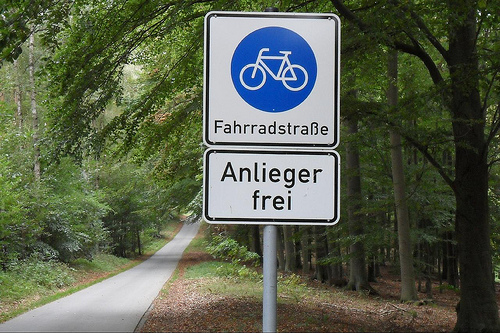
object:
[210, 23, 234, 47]
part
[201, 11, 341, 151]
board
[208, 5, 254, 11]
edge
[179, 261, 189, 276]
edge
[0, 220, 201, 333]
road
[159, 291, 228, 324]
ground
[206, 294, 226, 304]
leave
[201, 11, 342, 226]
sign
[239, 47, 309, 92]
bicycle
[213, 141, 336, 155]
path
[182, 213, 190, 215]
light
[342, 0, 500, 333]
tree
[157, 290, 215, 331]
sidewal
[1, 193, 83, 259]
plane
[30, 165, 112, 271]
hill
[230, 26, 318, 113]
circle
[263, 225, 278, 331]
pole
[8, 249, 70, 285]
bush